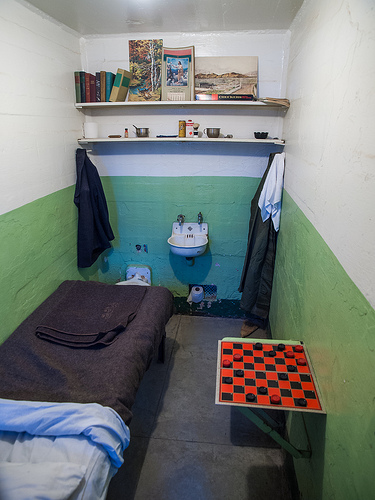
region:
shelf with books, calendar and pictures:
[64, 30, 289, 114]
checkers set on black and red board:
[210, 323, 322, 459]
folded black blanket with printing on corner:
[30, 271, 150, 367]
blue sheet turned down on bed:
[0, 378, 132, 468]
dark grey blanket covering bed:
[0, 270, 173, 420]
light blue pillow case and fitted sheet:
[2, 437, 104, 497]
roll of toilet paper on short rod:
[176, 275, 208, 313]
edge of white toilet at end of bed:
[109, 251, 154, 296]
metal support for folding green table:
[207, 400, 333, 485]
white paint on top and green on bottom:
[306, 141, 367, 362]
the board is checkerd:
[210, 324, 330, 425]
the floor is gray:
[162, 361, 195, 455]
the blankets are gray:
[32, 290, 114, 393]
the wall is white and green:
[23, 173, 78, 282]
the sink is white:
[162, 183, 210, 272]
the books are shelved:
[68, 62, 139, 103]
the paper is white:
[175, 279, 215, 316]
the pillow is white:
[4, 440, 95, 498]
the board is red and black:
[204, 319, 341, 429]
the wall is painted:
[305, 73, 351, 315]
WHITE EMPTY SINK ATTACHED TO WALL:
[165, 206, 212, 256]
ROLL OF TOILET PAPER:
[189, 280, 209, 306]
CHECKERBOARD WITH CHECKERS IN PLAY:
[214, 335, 323, 414]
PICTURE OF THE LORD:
[161, 53, 192, 85]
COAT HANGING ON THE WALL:
[68, 144, 116, 269]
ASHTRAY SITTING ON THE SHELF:
[250, 126, 283, 147]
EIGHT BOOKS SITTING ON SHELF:
[72, 66, 129, 111]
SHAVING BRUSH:
[188, 117, 203, 142]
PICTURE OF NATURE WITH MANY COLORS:
[126, 36, 166, 107]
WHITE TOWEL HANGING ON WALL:
[258, 151, 291, 230]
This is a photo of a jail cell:
[21, 48, 372, 397]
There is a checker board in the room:
[0, 198, 359, 499]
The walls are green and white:
[28, 37, 349, 495]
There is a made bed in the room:
[18, 280, 159, 495]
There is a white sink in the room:
[70, 134, 320, 438]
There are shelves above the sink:
[81, 33, 341, 225]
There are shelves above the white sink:
[41, 22, 315, 308]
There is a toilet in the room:
[95, 212, 204, 341]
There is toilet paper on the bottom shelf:
[56, 85, 228, 163]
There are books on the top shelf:
[78, 33, 183, 122]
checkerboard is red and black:
[203, 326, 342, 425]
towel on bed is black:
[29, 266, 168, 351]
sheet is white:
[1, 392, 131, 465]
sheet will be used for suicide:
[1, 384, 142, 476]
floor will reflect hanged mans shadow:
[134, 313, 241, 482]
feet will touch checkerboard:
[205, 316, 330, 429]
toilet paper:
[184, 273, 212, 320]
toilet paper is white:
[184, 280, 211, 330]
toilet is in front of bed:
[114, 263, 159, 294]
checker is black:
[218, 335, 281, 354]